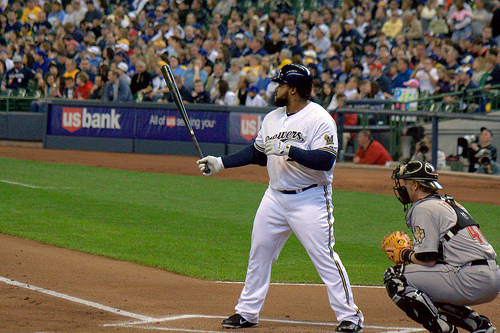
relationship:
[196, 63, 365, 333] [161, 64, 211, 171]
batter holding bat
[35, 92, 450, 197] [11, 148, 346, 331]
ads on side fo field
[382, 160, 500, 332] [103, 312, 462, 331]
catcher behind home plate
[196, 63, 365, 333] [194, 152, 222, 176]
batter has a right hand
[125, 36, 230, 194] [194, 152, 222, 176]
bat in right hand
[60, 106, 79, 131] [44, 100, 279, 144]
shield on a tarp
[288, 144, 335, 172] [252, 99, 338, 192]
sleeve under shirt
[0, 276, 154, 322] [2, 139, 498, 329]
base line on a field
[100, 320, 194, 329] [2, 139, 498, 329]
lines on a field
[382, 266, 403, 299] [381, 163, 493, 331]
knee guard on catcher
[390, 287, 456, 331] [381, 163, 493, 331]
leg guard on catcher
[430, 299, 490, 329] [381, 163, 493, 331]
leg guard on catcher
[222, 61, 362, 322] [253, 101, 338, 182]
batter wearing a shirt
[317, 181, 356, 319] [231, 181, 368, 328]
stripe on pants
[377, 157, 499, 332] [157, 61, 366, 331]
catcher behind batter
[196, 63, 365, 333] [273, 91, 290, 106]
batter has black beard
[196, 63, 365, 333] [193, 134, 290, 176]
batter wearing gloves